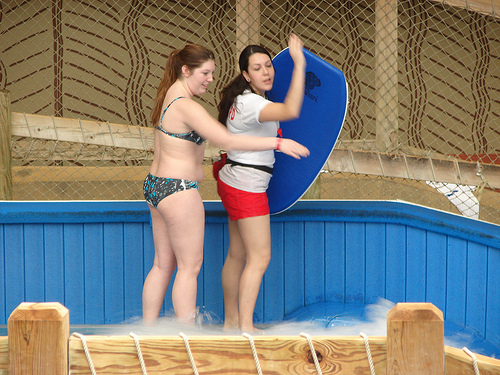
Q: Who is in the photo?
A: Two women.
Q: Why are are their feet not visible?
A: Because they are standing in water.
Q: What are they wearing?
A: Swimwear.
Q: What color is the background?
A: Blue and beige.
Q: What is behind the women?
A: A fence.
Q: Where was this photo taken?
A: A water park.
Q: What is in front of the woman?
A: A wooden rail.